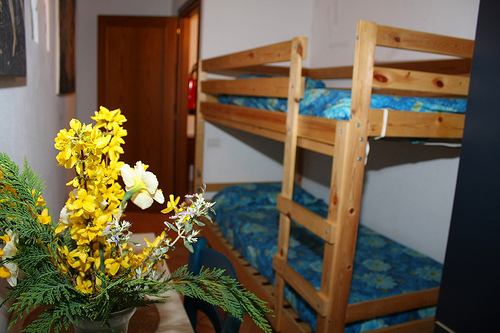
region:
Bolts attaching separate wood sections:
[337, 119, 367, 164]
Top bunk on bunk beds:
[198, 20, 478, 140]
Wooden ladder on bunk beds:
[269, 115, 346, 331]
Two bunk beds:
[200, 17, 482, 332]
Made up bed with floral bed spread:
[204, 182, 446, 328]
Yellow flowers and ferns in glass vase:
[1, 102, 276, 331]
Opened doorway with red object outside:
[158, 8, 203, 193]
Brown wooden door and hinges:
[93, 7, 186, 212]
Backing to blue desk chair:
[176, 237, 241, 330]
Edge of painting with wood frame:
[0, 2, 30, 92]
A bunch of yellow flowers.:
[59, 109, 124, 294]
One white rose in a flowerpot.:
[112, 154, 165, 211]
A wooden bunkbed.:
[194, 20, 493, 332]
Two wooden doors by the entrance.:
[94, 7, 212, 215]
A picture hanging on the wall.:
[2, 3, 32, 93]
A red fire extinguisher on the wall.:
[184, 57, 201, 114]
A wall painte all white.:
[223, 0, 483, 20]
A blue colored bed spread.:
[235, 192, 453, 311]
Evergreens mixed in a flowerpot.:
[1, 270, 278, 331]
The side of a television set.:
[435, 0, 498, 330]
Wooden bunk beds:
[201, 19, 473, 331]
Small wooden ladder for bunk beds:
[273, 20, 350, 330]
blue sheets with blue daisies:
[205, 179, 442, 331]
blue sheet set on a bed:
[216, 72, 465, 118]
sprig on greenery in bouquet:
[146, 264, 274, 331]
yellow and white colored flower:
[121, 161, 163, 208]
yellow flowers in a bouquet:
[28, 105, 185, 292]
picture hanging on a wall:
[56, 1, 77, 96]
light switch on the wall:
[206, 134, 221, 146]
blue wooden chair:
[183, 236, 243, 331]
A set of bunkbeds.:
[204, 20, 441, 332]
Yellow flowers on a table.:
[0, 105, 192, 331]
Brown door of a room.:
[93, 2, 204, 212]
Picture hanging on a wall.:
[54, 1, 79, 99]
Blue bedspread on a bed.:
[198, 180, 443, 330]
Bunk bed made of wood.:
[204, 12, 454, 332]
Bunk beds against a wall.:
[206, 25, 460, 332]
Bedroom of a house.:
[2, 3, 498, 328]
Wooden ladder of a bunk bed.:
[267, 18, 369, 332]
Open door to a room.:
[89, 0, 205, 217]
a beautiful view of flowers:
[26, 108, 178, 268]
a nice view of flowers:
[21, 78, 221, 328]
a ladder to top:
[244, 55, 393, 325]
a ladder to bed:
[246, 43, 408, 329]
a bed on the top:
[159, 32, 489, 185]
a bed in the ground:
[218, 192, 373, 317]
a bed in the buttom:
[241, 194, 376, 318]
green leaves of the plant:
[142, 272, 263, 328]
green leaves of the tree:
[5, 255, 105, 325]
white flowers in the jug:
[110, 140, 200, 260]